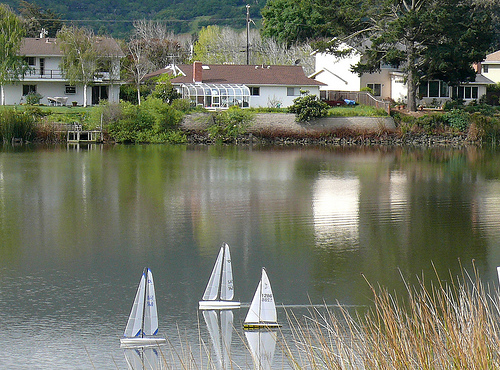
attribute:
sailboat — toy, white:
[121, 265, 168, 347]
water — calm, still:
[0, 143, 499, 368]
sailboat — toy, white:
[199, 242, 241, 312]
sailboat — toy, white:
[243, 266, 281, 330]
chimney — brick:
[192, 60, 203, 84]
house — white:
[130, 63, 323, 109]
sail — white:
[122, 268, 161, 338]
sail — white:
[200, 244, 235, 299]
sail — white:
[241, 269, 279, 322]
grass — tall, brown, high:
[265, 257, 499, 370]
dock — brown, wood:
[0, 115, 105, 145]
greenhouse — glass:
[172, 83, 250, 109]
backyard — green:
[0, 105, 151, 134]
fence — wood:
[319, 90, 393, 111]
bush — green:
[107, 94, 187, 144]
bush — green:
[202, 103, 255, 147]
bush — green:
[0, 109, 33, 143]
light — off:
[244, 3, 252, 13]